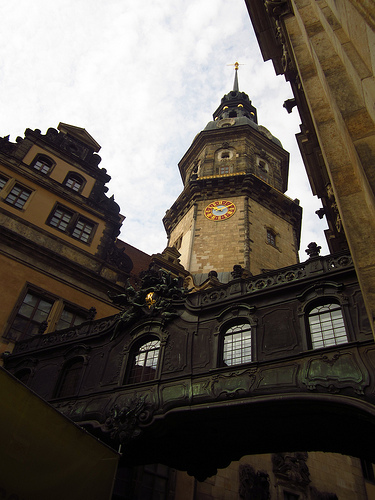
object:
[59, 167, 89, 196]
window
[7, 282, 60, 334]
window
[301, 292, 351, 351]
window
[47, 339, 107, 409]
window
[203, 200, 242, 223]
clock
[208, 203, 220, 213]
clock hand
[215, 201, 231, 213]
clock hand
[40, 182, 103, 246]
window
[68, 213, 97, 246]
window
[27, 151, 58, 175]
window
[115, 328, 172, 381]
window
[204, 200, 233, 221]
roman numerals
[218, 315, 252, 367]
window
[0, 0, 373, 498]
bulding